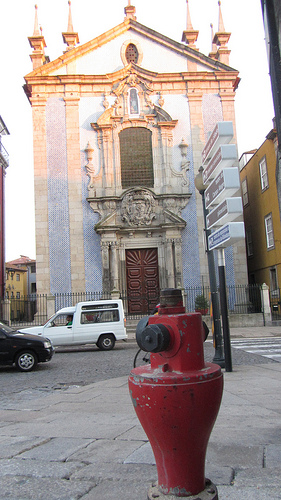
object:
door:
[126, 264, 144, 314]